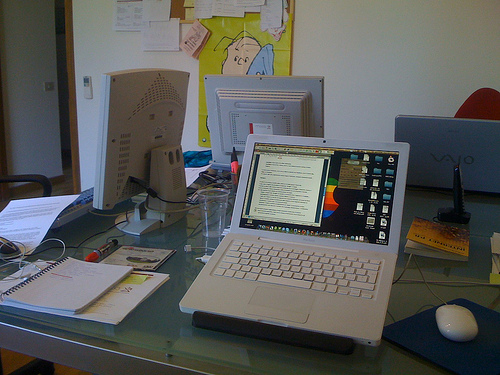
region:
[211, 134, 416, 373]
white laptop on table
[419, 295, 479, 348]
white mouse on mousepad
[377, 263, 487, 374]
blue mousepad on table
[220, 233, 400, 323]
white keyboard on laptop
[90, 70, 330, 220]
two white monitors on table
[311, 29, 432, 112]
white wall behind table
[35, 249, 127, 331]
white notebook on table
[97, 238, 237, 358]
computer table is blue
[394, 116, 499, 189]
grey laptop in background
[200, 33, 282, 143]
green poster behind monitor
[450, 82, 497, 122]
Top of red office chair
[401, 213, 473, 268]
Book with orange cover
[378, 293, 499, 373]
Black mouse pad to the left of the laptop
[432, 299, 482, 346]
White mouse on black mousepad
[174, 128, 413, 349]
Open laptop with document open on the screen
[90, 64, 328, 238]
The back of two monitors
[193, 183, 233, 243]
Empty clear plastic glass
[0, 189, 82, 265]
Printed white piece of paper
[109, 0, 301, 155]
Bulletin board area with postings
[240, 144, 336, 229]
Open document on the laptop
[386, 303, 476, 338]
corded white plastic computer mouse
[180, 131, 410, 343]
small silver gray Apple laptop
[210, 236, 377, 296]
integral laptop keyboard with gray plastic keys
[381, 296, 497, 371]
blue rectangular neoprene mousepad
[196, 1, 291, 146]
Peanuts poster of Linus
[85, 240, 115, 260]
red marker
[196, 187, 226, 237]
clear plastic drinking glass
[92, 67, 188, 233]
stand-up computer monitor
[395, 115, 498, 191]
silver Sony Vaio laptop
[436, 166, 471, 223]
network wireless equipment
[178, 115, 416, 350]
A computer laptop in the foreground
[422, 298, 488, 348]
A white computer mouse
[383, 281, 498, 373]
A computer mousepad in the foreground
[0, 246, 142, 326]
A notebook in the foreground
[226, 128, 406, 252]
Computer laptop screen is on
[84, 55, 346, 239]
Two computer monitors in the background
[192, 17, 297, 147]
A poster in the background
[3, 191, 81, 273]
A sheet of paper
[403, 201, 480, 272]
A book in the background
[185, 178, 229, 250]
A clear cup in the background